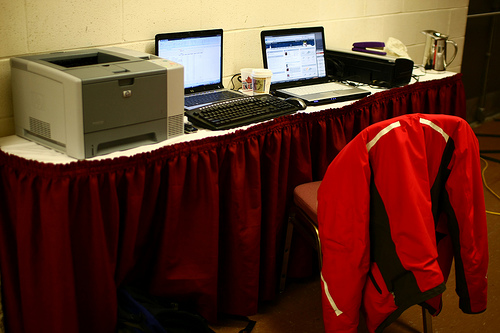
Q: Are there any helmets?
A: No, there are no helmets.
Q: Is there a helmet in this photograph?
A: No, there are no helmets.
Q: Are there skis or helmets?
A: No, there are no helmets or skis.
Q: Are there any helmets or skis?
A: No, there are no helmets or skis.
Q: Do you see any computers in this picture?
A: Yes, there is a computer.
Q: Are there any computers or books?
A: Yes, there is a computer.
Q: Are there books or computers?
A: Yes, there is a computer.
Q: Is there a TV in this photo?
A: No, there are no televisions.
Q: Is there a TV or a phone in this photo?
A: No, there are no televisions or phones.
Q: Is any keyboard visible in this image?
A: Yes, there is a keyboard.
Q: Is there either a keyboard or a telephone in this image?
A: Yes, there is a keyboard.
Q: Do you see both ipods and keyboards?
A: No, there is a keyboard but no ipods.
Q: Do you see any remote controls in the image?
A: No, there are no remote controls.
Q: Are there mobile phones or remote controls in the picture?
A: No, there are no remote controls or mobile phones.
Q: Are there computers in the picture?
A: Yes, there is a computer.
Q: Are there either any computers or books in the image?
A: Yes, there is a computer.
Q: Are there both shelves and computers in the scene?
A: No, there is a computer but no shelves.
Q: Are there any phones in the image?
A: No, there are no phones.